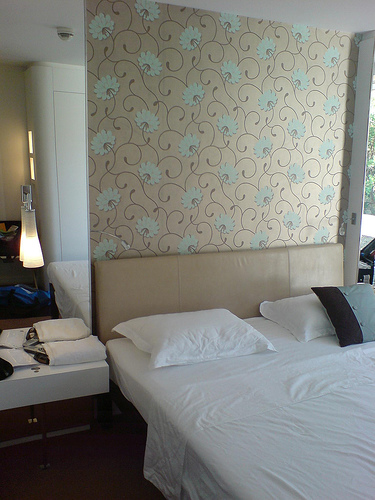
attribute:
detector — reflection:
[55, 25, 74, 41]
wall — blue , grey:
[84, 0, 347, 258]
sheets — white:
[196, 367, 337, 426]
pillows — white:
[117, 303, 339, 361]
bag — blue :
[1, 279, 59, 320]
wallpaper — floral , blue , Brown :
[84, 5, 345, 249]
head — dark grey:
[115, 236, 352, 343]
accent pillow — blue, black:
[313, 285, 373, 351]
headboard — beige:
[95, 241, 350, 345]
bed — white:
[149, 313, 345, 451]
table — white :
[0, 366, 128, 409]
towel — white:
[39, 318, 79, 336]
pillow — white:
[113, 303, 273, 374]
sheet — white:
[105, 315, 374, 498]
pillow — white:
[125, 309, 280, 371]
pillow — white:
[258, 294, 328, 344]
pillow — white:
[314, 282, 371, 349]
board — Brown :
[67, 242, 373, 317]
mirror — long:
[5, 14, 131, 363]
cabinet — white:
[26, 61, 91, 268]